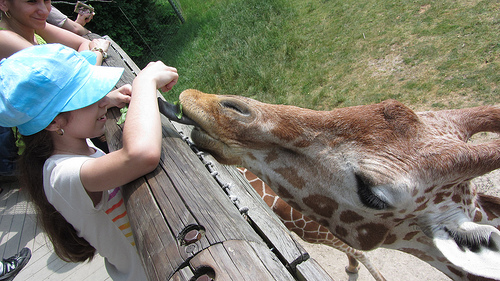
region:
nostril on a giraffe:
[217, 93, 255, 120]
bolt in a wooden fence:
[182, 265, 212, 279]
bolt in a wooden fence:
[177, 223, 202, 247]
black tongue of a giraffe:
[157, 90, 187, 124]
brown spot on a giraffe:
[300, 187, 343, 218]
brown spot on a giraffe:
[260, 144, 282, 166]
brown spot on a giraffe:
[268, 160, 308, 190]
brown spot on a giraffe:
[448, 190, 464, 205]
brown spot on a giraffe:
[431, 187, 446, 209]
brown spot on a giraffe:
[421, 180, 435, 196]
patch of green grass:
[167, 33, 239, 89]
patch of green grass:
[240, 47, 325, 92]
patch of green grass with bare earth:
[330, 55, 415, 97]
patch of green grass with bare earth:
[431, 68, 499, 105]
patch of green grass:
[420, 1, 499, 62]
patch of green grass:
[317, 3, 411, 53]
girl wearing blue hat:
[3, 38, 169, 278]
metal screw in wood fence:
[172, 218, 214, 250]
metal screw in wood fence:
[187, 257, 222, 279]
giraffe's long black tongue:
[157, 85, 217, 142]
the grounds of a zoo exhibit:
[0, 0, 499, 280]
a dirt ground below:
[290, 230, 453, 280]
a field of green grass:
[154, 0, 499, 105]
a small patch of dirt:
[370, 52, 403, 74]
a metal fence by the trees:
[97, 0, 187, 70]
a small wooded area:
[50, 0, 182, 70]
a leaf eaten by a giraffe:
[171, 100, 182, 119]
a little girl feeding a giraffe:
[0, 43, 179, 280]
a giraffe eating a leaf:
[157, 88, 499, 280]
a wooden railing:
[80, 32, 333, 279]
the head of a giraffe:
[175, 86, 496, 252]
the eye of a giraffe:
[347, 165, 404, 220]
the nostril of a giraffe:
[212, 94, 259, 122]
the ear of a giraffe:
[428, 206, 495, 277]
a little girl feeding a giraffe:
[11, 44, 456, 258]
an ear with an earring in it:
[42, 114, 68, 139]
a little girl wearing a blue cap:
[0, 43, 175, 238]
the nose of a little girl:
[99, 96, 112, 113]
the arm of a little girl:
[93, 58, 173, 187]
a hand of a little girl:
[140, 54, 184, 91]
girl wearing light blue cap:
[0, 44, 181, 279]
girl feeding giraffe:
[2, 42, 497, 279]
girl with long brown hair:
[0, 43, 176, 279]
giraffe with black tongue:
[156, 89, 497, 279]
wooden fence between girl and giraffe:
[94, 42, 336, 279]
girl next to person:
[1, 43, 177, 278]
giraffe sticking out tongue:
[158, 86, 497, 279]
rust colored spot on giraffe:
[302, 193, 337, 220]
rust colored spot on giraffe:
[269, 166, 306, 191]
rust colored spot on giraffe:
[414, 195, 425, 203]